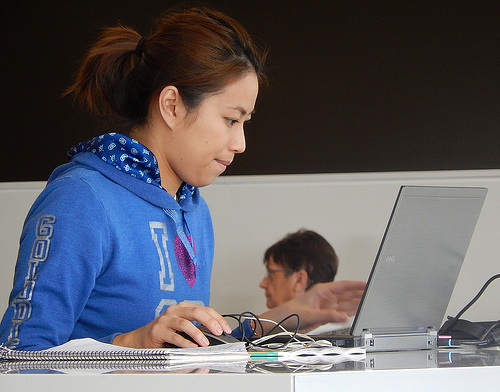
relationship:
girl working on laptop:
[0, 6, 270, 353] [251, 181, 491, 355]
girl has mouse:
[0, 6, 270, 353] [178, 326, 248, 351]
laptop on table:
[251, 181, 491, 355] [1, 341, 500, 390]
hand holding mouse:
[118, 299, 234, 352] [178, 326, 248, 351]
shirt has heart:
[0, 130, 215, 355] [175, 233, 200, 288]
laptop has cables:
[251, 181, 491, 355] [224, 311, 334, 354]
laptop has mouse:
[251, 181, 491, 355] [178, 326, 248, 351]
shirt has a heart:
[0, 130, 215, 355] [175, 233, 200, 288]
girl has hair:
[0, 6, 270, 353] [57, 6, 272, 126]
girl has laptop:
[0, 6, 270, 353] [251, 181, 491, 355]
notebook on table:
[0, 337, 252, 364] [1, 341, 500, 390]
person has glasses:
[259, 227, 339, 311] [265, 267, 286, 279]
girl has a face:
[0, 6, 270, 353] [187, 74, 259, 191]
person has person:
[259, 227, 339, 311] [259, 227, 339, 311]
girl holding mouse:
[0, 6, 270, 353] [178, 326, 248, 351]